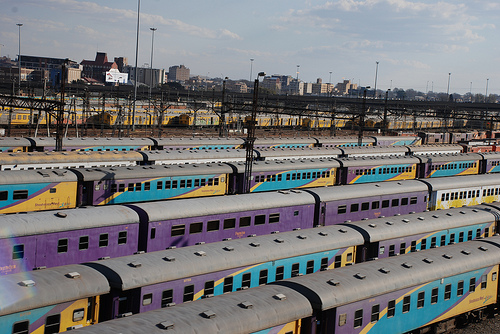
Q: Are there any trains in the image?
A: Yes, there is a train.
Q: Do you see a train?
A: Yes, there is a train.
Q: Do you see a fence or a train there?
A: Yes, there is a train.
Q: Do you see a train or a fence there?
A: Yes, there is a train.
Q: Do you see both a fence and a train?
A: No, there is a train but no fences.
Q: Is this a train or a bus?
A: This is a train.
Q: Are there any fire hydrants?
A: No, there are no fire hydrants.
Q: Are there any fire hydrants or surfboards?
A: No, there are no fire hydrants or surfboards.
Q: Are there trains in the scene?
A: Yes, there is a train.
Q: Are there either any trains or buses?
A: Yes, there is a train.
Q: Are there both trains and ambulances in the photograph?
A: No, there is a train but no ambulances.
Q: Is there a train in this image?
A: Yes, there is a train.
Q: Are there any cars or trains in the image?
A: Yes, there is a train.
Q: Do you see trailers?
A: No, there are no trailers.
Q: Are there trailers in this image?
A: No, there are no trailers.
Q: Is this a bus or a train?
A: This is a train.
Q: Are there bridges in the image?
A: Yes, there is a bridge.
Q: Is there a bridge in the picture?
A: Yes, there is a bridge.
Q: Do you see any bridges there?
A: Yes, there is a bridge.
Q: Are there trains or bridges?
A: Yes, there is a bridge.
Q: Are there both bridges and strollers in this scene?
A: No, there is a bridge but no strollers.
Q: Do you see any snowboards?
A: No, there are no snowboards.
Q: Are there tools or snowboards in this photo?
A: No, there are no snowboards or tools.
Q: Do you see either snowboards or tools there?
A: No, there are no snowboards or tools.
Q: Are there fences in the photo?
A: No, there are no fences.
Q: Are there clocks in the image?
A: No, there are no clocks.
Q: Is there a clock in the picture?
A: No, there are no clocks.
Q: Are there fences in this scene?
A: No, there are no fences.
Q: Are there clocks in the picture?
A: No, there are no clocks.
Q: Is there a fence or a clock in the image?
A: No, there are no clocks or fences.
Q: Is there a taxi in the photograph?
A: No, there are no taxis.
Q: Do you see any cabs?
A: No, there are no cabs.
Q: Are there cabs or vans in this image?
A: No, there are no cabs or vans.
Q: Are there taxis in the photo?
A: No, there are no taxis.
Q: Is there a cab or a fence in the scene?
A: No, there are no taxis or fences.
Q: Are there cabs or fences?
A: No, there are no cabs or fences.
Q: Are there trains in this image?
A: Yes, there is a train.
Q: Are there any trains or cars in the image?
A: Yes, there is a train.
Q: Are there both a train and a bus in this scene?
A: No, there is a train but no buses.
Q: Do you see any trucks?
A: No, there are no trucks.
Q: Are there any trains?
A: Yes, there is a train.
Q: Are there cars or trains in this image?
A: Yes, there is a train.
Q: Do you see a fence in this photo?
A: No, there are no fences.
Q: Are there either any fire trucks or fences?
A: No, there are no fences or fire trucks.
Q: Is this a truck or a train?
A: This is a train.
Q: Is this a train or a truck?
A: This is a train.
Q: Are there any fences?
A: No, there are no fences.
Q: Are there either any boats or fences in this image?
A: No, there are no fences or boats.